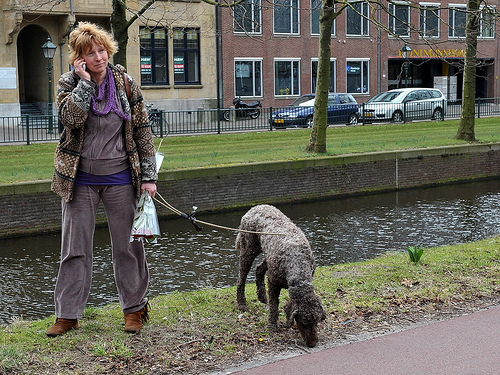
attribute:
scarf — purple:
[86, 66, 128, 125]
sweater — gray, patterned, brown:
[51, 64, 159, 201]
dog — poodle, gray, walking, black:
[234, 204, 327, 348]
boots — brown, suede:
[44, 301, 152, 335]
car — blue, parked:
[271, 93, 360, 128]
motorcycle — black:
[222, 96, 261, 120]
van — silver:
[358, 87, 446, 119]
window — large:
[173, 29, 203, 83]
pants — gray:
[50, 182, 149, 316]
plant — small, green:
[406, 242, 424, 259]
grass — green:
[0, 118, 499, 185]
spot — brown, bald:
[34, 301, 462, 374]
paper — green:
[130, 151, 164, 244]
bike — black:
[146, 104, 167, 131]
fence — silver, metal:
[1, 101, 499, 146]